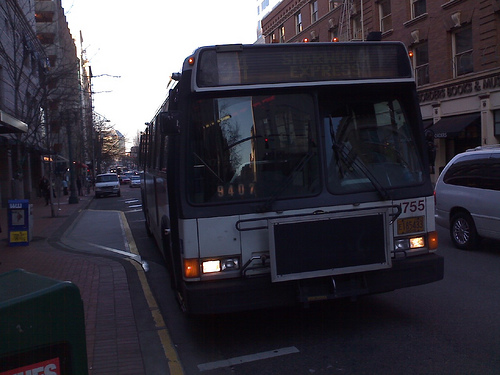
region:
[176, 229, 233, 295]
Lights on a bus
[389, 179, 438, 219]
Number on a bus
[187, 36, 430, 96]
Sign on a bus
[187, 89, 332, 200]
Window on a bus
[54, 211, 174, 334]
Curb by a street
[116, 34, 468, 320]
Bus on a road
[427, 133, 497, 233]
White van on a road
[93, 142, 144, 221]
Cars on a street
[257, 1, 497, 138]
Building by a road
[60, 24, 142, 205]
Trees by a road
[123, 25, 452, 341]
a bus on side of street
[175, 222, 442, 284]
headlights of bus is turn on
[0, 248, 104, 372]
a green trash can on a street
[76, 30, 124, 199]
poles on left side of street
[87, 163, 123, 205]
a white car is parking on left side of street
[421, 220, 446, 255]
right signal light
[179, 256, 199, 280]
left signal light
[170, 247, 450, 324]
bumper of bus is black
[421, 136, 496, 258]
a van on a street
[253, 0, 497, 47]
a red building of four floors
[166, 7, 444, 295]
this is a big bus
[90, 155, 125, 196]
a car in the picture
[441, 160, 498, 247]
a car in the picture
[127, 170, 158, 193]
a car in the picture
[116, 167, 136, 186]
a car in the picture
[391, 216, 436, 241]
number plate of the bus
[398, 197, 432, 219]
these are numbers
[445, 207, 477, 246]
the Tyre of the car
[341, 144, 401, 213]
this is a windscreen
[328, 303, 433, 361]
tarmaked road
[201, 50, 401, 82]
The marquee display on the front of the bus.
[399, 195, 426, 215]
The number 755 on the front of the bus.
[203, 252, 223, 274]
The left headlight on the front of the bus.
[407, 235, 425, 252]
The right headlight on the front of the bus.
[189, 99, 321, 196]
The left main window on the front of the bus.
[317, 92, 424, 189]
The right main window on the front of the bus.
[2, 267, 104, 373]
The green bin in the left hand corner.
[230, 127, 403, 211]
The windshield wipers on the front of the bus.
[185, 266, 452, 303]
The black fender on the front of the bus.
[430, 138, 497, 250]
The back of the mini van on the right.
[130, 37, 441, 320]
front of public bus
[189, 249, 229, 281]
glowing headlight on bus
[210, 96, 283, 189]
reflection on bus windshield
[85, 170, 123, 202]
white van parked on street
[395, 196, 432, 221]
three numbers on bus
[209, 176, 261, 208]
glowing numbers behind windshield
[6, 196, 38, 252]
blue newspaper dispenser on sidewalk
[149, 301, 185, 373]
yellow paint on curb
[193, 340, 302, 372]
white stripe on street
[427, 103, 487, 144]
black awning on building